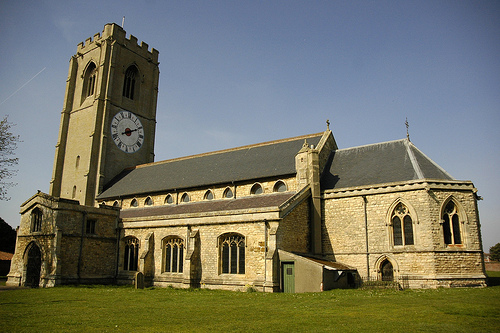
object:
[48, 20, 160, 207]
chapel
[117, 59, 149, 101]
windows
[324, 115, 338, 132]
crucifix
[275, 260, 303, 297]
door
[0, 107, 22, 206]
branches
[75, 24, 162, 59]
roof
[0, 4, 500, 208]
sky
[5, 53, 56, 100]
trail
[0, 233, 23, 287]
building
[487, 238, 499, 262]
tree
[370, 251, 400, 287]
thos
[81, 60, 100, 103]
window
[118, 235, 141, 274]
window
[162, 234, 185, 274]
window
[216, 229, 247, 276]
window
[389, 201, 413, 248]
window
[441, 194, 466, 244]
window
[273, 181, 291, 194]
window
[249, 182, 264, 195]
window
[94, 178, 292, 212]
ten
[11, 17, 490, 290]
building